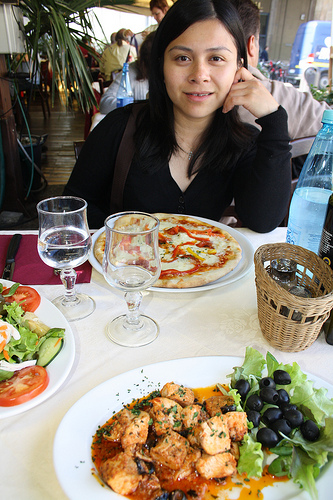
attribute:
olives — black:
[233, 369, 331, 455]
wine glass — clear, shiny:
[98, 209, 168, 350]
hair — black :
[111, 1, 276, 196]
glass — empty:
[90, 211, 170, 351]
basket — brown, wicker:
[252, 235, 332, 361]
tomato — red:
[0, 361, 51, 409]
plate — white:
[0, 274, 78, 420]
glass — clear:
[29, 194, 102, 327]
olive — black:
[272, 370, 291, 386]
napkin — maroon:
[12, 239, 94, 288]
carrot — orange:
[51, 330, 63, 345]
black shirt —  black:
[54, 93, 295, 237]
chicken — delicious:
[103, 377, 246, 493]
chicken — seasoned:
[151, 402, 234, 478]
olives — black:
[248, 375, 294, 423]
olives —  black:
[235, 383, 297, 441]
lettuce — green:
[232, 360, 285, 459]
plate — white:
[89, 211, 253, 295]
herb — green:
[238, 348, 332, 480]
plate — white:
[48, 361, 332, 499]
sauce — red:
[97, 427, 292, 497]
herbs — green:
[225, 347, 331, 498]